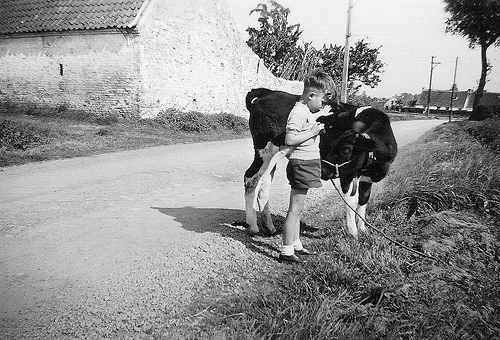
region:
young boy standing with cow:
[274, 68, 336, 272]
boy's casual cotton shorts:
[282, 155, 325, 193]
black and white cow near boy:
[232, 83, 402, 253]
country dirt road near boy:
[0, 105, 479, 337]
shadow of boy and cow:
[145, 197, 332, 270]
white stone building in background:
[1, 3, 306, 122]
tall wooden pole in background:
[421, 53, 443, 118]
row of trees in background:
[237, 2, 384, 107]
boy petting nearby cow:
[273, 70, 338, 267]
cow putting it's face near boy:
[238, 83, 400, 247]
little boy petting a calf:
[229, 64, 413, 261]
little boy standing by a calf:
[222, 53, 409, 269]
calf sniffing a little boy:
[231, 56, 409, 271]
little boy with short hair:
[263, 62, 341, 267]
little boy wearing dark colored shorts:
[268, 55, 341, 267]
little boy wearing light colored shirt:
[268, 63, 342, 270]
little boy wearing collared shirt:
[272, 58, 346, 277]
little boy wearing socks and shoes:
[268, 60, 343, 274]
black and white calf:
[231, 78, 405, 249]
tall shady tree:
[434, 3, 498, 125]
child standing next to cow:
[240, 43, 397, 268]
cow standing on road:
[240, 58, 407, 278]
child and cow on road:
[240, 53, 398, 268]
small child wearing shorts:
[280, 159, 330, 191]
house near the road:
[3, 1, 254, 173]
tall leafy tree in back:
[445, 0, 497, 124]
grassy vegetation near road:
[346, 245, 444, 335]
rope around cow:
[317, 139, 439, 281]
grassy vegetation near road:
[412, 153, 480, 228]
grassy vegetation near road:
[445, 109, 495, 176]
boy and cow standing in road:
[225, 55, 409, 268]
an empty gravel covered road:
[12, 160, 223, 328]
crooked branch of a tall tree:
[468, 35, 491, 120]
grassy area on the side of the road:
[432, 116, 499, 329]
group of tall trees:
[237, 3, 384, 90]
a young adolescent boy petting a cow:
[271, 63, 338, 275]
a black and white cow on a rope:
[223, 85, 395, 248]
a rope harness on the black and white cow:
[314, 153, 486, 304]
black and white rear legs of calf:
[241, 136, 284, 234]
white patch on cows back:
[351, 103, 373, 118]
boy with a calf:
[242, 69, 397, 251]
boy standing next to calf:
[280, 70, 345, 268]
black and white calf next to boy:
[238, 82, 398, 268]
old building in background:
[1, 1, 252, 117]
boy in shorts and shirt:
[279, 62, 343, 267]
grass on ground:
[226, 125, 497, 336]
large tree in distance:
[436, 0, 498, 121]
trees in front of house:
[251, 2, 392, 95]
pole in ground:
[342, 3, 353, 113]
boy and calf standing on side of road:
[15, 86, 421, 338]